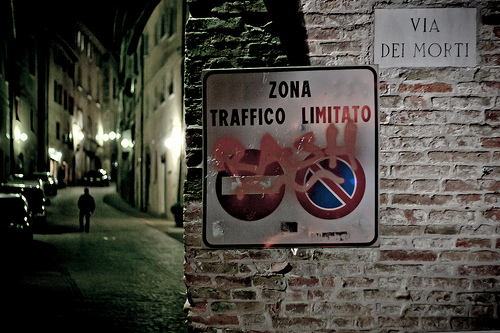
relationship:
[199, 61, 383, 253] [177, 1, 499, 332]
traffic sign on wall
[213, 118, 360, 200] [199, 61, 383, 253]
graffiti painted on sign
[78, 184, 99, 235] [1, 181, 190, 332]
person walking up street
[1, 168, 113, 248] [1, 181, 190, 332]
automobiles are parked along street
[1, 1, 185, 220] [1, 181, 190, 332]
buildings are along sides of street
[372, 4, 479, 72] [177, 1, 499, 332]
name plaque on part of wall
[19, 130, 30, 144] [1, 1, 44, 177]
light on building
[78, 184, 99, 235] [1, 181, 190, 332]
person walking down street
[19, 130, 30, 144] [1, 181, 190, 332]
light along wall of street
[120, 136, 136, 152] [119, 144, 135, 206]
window above archway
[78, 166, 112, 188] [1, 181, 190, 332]
car parked on side of street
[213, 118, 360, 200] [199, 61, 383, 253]
graffiti on traffic sign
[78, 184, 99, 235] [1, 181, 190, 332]
person walking alone on street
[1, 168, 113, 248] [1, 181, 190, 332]
automobiles are parked on street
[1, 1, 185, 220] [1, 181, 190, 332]
buildings are along street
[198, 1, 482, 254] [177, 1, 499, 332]
signs are on wall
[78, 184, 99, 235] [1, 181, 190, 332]
person walking on street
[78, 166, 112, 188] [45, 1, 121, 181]
car parked beside building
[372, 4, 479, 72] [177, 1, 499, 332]
name plaque on wall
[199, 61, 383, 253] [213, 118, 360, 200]
traffic sign has graffiti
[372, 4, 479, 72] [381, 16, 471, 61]
name plaque says via dei morti